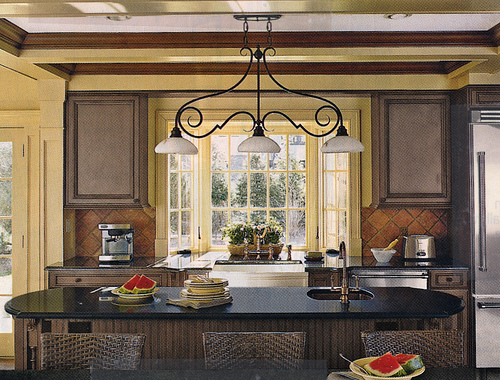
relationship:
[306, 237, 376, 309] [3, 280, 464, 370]
sink in island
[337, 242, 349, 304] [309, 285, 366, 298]
faucet above sink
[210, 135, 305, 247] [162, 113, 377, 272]
frame in center of window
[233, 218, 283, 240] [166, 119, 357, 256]
plant sitting near window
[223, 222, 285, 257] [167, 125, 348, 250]
plants by window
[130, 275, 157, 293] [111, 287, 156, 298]
watermelon on plate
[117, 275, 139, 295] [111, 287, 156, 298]
watermelon on plate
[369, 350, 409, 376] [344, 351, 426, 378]
watermelon in bowl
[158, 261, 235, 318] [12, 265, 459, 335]
plates on counter